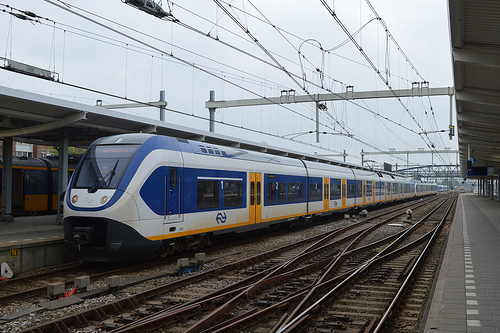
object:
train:
[58, 127, 446, 263]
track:
[311, 193, 457, 326]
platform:
[6, 192, 106, 271]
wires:
[367, 0, 452, 186]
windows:
[192, 176, 221, 213]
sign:
[460, 149, 497, 177]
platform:
[415, 181, 499, 332]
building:
[6, 133, 68, 160]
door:
[244, 163, 266, 228]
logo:
[208, 209, 230, 227]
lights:
[96, 189, 112, 206]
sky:
[28, 6, 433, 124]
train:
[5, 149, 77, 213]